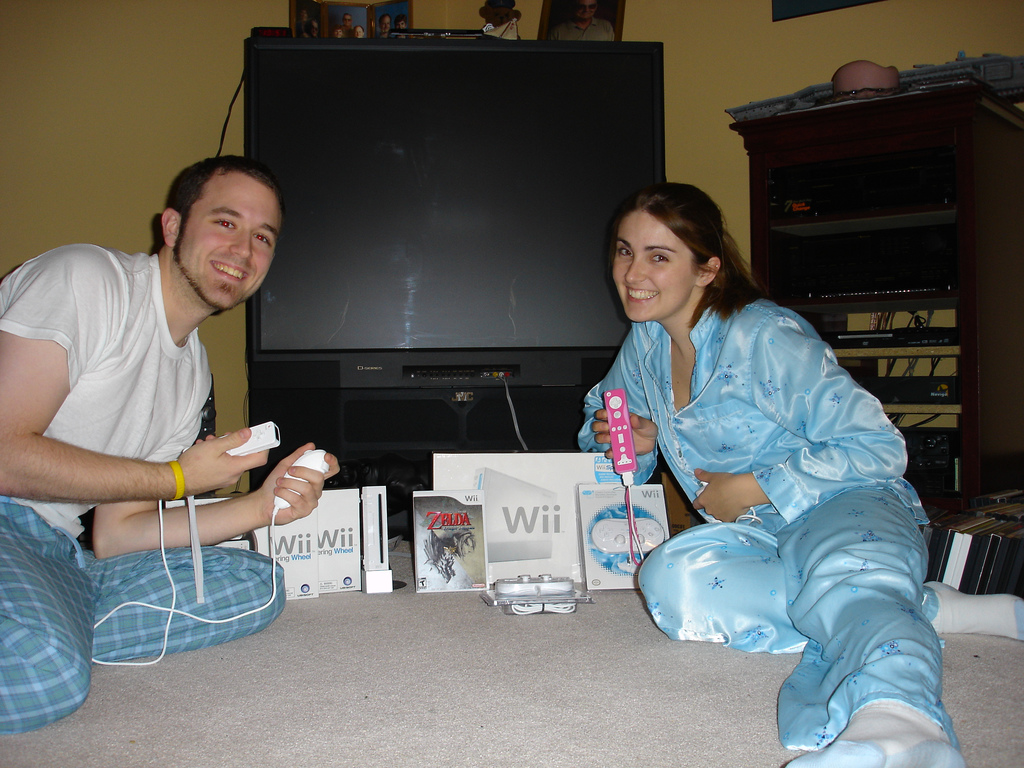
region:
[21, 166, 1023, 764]
A young couple in pajamas.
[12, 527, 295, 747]
His blue flannel pants.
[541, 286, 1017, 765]
Her blue two piece pajamas.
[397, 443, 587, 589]
The Zelda game for Wii System.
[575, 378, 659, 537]
A pink and white Wii controller.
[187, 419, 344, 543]
Two white Wii controllers.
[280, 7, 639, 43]
Four family photos in a row.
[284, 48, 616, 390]
A large screen television.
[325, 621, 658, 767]
Gray rug on the floor.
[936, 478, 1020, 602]
A pile of books on the floor.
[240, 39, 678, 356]
Screen on projection television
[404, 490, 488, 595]
Zelda game for the Wii console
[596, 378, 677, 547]
pink controller for Wii console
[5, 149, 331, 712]
male smiling with new game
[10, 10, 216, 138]
yellow wall of room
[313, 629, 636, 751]
carpet not showing any stains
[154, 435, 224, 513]
yellow bracelet on male's right wrist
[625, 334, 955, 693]
female's blue pajamas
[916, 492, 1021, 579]
dvd movies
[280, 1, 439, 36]
pictures on top of tv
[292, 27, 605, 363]
Big television screen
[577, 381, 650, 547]
A pink Wii remote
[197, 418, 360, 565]
His remote is white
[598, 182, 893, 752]
Her PJ's are satiny blue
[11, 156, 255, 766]
His pajama bottom are blue plaid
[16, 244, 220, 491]
His tee shirt is white.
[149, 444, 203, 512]
A yellow bracelet on his wrist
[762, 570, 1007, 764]
Her socks are white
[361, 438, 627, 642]
The complete Wii game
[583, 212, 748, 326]
She has a big smile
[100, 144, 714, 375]
the people are smiling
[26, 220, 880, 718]
it is an indoor scene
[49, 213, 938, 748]
there are two people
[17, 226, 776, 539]
they are holding wii controllers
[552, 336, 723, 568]
the woman is holding a pink contoller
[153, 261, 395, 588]
the man is holding a white controller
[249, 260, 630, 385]
there is a television behind the people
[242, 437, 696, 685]
there are wii boxes on the floor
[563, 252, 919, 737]
the woman is wearing light blue cloth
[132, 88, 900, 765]
it appears to be a living room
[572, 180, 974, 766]
woman in blue pajamas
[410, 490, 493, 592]
Zelda Wii game in box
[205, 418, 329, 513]
two white Wii controllers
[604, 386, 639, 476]
one pink Wii controller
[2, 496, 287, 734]
man's blue plaid pajama bottoms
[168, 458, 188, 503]
yellow 'Livestrong' encouragement bracelet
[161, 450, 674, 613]
multiple Wii game accessories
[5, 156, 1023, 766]
smiling and happy couple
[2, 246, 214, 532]
plain white t-shirt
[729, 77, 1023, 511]
stereo and electronics cabinet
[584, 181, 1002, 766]
The woman is wearing silk pajamas.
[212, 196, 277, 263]
mans eyes are red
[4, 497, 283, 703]
man wearing blue flannel pants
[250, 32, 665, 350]
large television is turned off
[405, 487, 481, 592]
a video game on the carpet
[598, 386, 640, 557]
pink game controller in woman's hand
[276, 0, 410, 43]
photographs on top of television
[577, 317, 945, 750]
woman wearing blue sleeping attire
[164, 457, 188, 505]
yellow armband around man's right wrist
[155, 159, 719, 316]
man and woman smiling broadly